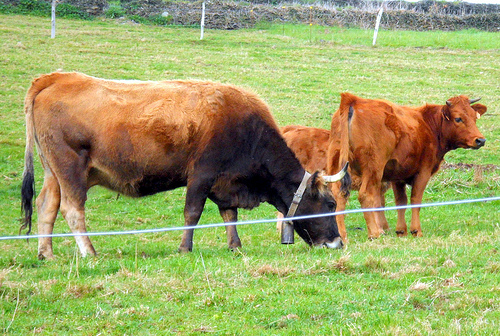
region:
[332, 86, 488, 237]
medium orange cow with horns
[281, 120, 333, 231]
part of an orange cow next to cow with horns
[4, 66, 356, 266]
large orange cow with black face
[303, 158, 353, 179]
horns on cow with black face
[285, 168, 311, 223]
collar on cow with black face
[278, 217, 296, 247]
bell on cow collar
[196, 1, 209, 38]
wooden fence post in the background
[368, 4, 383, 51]
wooden fence pole in the background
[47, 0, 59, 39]
wooden fence pole in the background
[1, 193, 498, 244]
fence wire surrounding the cows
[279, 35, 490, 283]
two brown cows grazing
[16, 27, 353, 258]
bull wearing collar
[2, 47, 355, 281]
bull eating green grass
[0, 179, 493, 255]
metal fence wire keeping cows in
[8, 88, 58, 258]
bull with black tail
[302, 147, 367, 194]
white and black horns on bull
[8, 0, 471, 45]
fence to keep cattle in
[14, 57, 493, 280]
grazing cattle in a pasture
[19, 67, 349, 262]
black and brown bull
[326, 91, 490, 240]
brown bull in grass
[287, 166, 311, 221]
fabric collar on cow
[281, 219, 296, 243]
metal bell on collar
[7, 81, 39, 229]
brown and black tail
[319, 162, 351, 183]
white horn on cow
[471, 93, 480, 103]
black horn on cow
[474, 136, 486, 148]
black nose on cow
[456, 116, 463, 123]
black eye on cow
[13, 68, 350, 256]
cow eating green grass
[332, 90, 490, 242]
Small red young cow.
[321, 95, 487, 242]
Red calf.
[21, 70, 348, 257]
Red and brown cow grazing.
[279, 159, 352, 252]
Cow with horns.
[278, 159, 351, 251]
Cow with horns wearing a bell.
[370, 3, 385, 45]
Wooden fence post.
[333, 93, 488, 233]
Small red calf with horns.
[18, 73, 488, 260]
Adult cow grazing with two younger cows.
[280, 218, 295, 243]
Cow bell.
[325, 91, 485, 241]
Young, red calf.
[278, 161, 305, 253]
bell around cows neck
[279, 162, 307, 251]
cow around neck of cow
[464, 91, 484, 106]
horn of a bull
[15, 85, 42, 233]
tail of a cow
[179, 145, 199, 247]
brown leg of a cow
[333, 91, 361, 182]
tail of a cow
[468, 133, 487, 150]
nose of a cow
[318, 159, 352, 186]
horn of a cow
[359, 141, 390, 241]
rear leg of a cow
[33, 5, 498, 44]
fence around perimeter of pasture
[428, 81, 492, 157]
face of a cow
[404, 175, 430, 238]
leg of a cow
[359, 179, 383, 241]
leg of a cow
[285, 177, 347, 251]
face of a cow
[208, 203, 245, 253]
leg of a cow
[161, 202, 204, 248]
leg of a cow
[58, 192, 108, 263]
leg of a cow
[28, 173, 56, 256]
leg of a cow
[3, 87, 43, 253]
tail of a cow